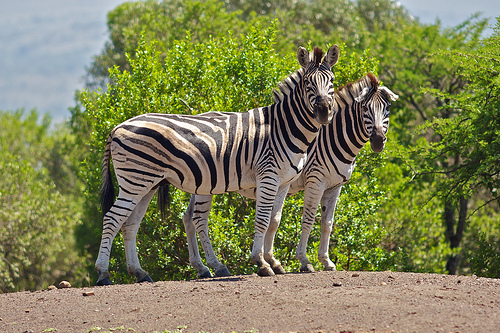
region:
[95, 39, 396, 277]
Two zebras side by side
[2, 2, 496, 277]
Trees behind zebras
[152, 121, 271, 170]
Stripes on side of zebra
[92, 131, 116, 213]
Tail of zebra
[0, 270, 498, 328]
Ground covered in sand and dirt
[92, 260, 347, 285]
Eight zebra hooves on the ground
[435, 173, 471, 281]
Two trunks of trees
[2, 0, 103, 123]
Blurry mountains off in the distance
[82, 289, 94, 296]
One of several rocks on the ground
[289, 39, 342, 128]
Zebra looking at the camera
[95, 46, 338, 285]
One of the two zebras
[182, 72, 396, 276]
Another zebra standing on four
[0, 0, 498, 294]
The thicket of green trees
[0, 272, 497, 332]
Brown soil the zebras are standing on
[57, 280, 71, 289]
A small stone on the ground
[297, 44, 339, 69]
Two erect ears of a zebra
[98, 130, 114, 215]
The tail of a zebra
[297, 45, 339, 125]
Head of a zebra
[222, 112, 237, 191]
One of the black stripe on zebra's body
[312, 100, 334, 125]
Nose and mouth of a zebra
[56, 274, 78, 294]
rock on the ground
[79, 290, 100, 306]
rock on the ground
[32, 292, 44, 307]
rock on the ground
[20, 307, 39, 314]
rock on the ground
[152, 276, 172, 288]
rock on the ground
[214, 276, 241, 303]
rock on the ground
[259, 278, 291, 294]
rock on the ground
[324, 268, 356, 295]
rock on the ground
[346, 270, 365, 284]
rock on the ground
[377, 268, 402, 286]
rock on the ground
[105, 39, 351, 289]
this is a zebra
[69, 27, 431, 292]
two zebras standing together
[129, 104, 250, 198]
black stripes on zebra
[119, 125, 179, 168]
grey stripe on zebra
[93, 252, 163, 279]
white ankles on zebra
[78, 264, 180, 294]
black hoofs of zebra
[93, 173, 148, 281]
back leg of zebra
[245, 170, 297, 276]
front legs of zebra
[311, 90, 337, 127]
black nose on zebra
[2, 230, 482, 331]
light brown dirt on ground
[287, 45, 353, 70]
Zebra has white ears.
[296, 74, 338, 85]
Zebra has dark eyes.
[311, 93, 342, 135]
Zebra has dark nose.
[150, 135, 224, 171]
Zebra is covered in stripes.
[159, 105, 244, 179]
Zebra is black and white.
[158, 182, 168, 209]
Black hair on tip of tail.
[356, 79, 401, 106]
Zebra has white ears.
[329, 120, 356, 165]
Zebra is black and white.